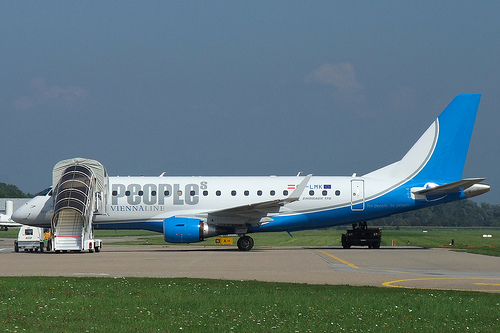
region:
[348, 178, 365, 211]
last door on plane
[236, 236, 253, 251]
back wheel on ground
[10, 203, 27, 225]
nose of airplane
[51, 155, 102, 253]
stairs connected to airplane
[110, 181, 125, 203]
first P on airplane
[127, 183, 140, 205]
first e on airplane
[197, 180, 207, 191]
big s on airplane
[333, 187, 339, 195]
last window on airplane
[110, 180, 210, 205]
big words on side of airplane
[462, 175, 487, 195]
very back end of airplane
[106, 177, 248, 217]
the word people on the plane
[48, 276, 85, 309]
grass field in front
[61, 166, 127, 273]
stairs to get into the plane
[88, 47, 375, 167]
partly cloudy sky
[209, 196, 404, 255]
the wings of the airplane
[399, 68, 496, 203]
the back of the airplane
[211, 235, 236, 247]
yellow sign markign the runway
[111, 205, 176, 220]
Vienna on the airplane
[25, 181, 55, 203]
the front window of the plane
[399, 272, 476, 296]
yellow markings on the run way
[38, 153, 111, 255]
Mobile staircase is attached to plane.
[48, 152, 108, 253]
Mobile staircase is covered.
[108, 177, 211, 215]
Peoples Viennaline is Austrian airline.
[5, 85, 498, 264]
Plane is a single Embraer 170 aircraft.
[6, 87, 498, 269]
Airplane is blue and white.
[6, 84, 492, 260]
Aircraft is on the ground.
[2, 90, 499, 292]
There are no people outside aircraft.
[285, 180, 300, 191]
Austrian flag above front wings.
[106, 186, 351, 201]
Windows indicate aircraft has 76 passenger seats.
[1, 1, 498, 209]
Sky is clear and blue.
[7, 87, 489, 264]
plane parked on tarmac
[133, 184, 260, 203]
windows on side of plane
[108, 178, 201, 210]
light gray letters on plane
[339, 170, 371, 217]
door on side of plane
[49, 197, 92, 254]
stairs for plane passenger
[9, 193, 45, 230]
nose on front of plane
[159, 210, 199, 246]
blue jet engine on side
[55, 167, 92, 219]
cover over plane stairs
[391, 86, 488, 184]
blue and white plane tail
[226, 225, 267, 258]
landing gear under plane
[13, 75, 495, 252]
the plane is white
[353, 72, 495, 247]
the tail of the plane is blue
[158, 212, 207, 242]
the engine on the plane is blue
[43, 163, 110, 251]
the ramp is parked at the plane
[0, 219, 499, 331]
the grass is green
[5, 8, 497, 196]
the sky is hazy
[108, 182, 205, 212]
the plane says PEOPLE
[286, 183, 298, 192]
a red and white striped flag is painted on the plane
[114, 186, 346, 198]
the plane has many windows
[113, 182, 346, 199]
the windows are round